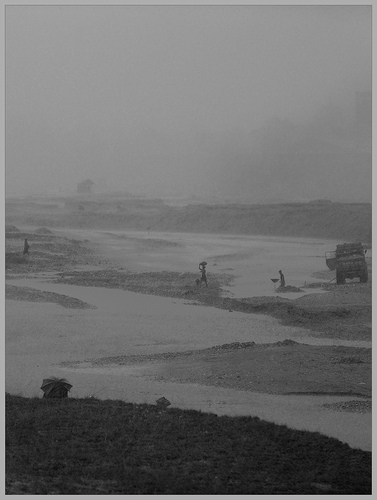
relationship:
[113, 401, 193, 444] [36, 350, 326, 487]
cow eating grass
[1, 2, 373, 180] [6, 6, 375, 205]
cloud in sky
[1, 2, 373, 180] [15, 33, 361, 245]
cloud in sky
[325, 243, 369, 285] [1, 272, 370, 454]
jeep near water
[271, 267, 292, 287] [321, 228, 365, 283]
human near vehicle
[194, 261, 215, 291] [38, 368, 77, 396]
person holding umbrella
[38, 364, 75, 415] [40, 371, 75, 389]
persons holding umbrella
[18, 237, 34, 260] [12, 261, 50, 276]
person walking across sand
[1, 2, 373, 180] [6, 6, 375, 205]
cloud are in sky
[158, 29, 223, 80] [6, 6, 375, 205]
cloud in sky